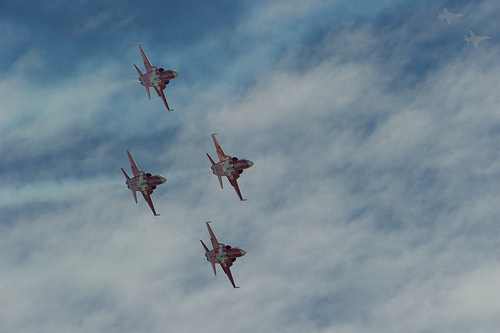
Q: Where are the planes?
A: In the air.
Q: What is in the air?
A: Planes.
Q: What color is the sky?
A: Blue.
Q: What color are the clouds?
A: White.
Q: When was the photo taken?
A: Daytime.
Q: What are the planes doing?
A: Flying.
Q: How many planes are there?
A: Four.